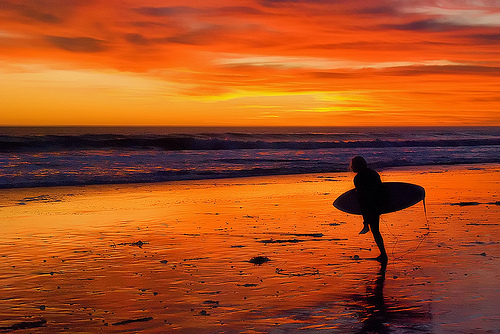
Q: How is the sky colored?
A: Orange, yellow and red.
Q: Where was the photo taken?
A: At the beach.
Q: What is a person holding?
A: Surfboard.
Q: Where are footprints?
A: On the sand.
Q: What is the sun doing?
A: Setting.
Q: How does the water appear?
A: Calm.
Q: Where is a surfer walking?
A: On the beach.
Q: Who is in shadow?
A: The surfer.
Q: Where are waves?
A: In the ocean.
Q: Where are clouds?
A: In the sky.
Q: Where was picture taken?
A: At a beach.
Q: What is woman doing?
A: Surfing.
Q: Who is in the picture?
A: A woman surfer.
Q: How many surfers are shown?
A: One.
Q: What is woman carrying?
A: Surfboard.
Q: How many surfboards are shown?
A: One.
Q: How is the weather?
A: Cloudy.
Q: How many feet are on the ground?
A: One.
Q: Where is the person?
A: Beach.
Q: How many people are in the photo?
A: One.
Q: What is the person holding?
A: Surfboard.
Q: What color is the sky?
A: Orange and yellow.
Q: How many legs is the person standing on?
A: One.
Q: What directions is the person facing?
A: Left.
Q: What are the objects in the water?
A: Waves.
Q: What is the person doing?
A: Carrying surfboard.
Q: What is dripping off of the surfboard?
A: Water.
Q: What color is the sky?
A: Orange.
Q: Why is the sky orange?
A: The sun is setting.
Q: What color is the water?
A: Blue.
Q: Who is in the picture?
A: A person.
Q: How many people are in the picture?
A: One.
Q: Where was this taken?
A: A beach.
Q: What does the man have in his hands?
A: Surfboard.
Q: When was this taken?
A: Evening.